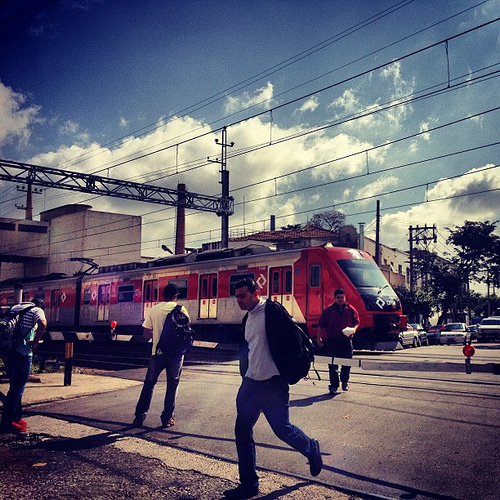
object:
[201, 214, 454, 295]
building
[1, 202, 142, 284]
building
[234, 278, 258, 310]
head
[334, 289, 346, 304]
head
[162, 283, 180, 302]
head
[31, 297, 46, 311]
head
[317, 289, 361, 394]
man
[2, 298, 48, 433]
man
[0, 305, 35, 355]
backpack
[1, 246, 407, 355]
train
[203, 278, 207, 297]
window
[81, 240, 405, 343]
tran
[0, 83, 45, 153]
cloud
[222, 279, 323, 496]
man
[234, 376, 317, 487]
pants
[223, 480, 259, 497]
foot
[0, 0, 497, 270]
cables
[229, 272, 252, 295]
window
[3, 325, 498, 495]
ground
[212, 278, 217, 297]
window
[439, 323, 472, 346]
car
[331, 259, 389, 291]
window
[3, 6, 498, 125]
sky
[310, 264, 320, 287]
window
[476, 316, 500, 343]
cars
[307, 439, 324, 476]
shoe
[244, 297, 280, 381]
shirt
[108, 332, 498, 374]
baracade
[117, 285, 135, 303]
small window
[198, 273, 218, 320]
door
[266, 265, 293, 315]
door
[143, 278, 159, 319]
door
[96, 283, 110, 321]
door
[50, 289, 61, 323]
door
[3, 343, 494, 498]
sidewalk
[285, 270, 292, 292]
window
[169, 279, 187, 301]
window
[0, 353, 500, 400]
track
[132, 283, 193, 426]
person